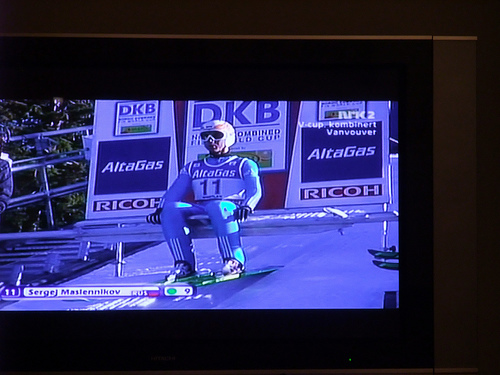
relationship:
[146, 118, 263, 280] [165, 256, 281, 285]
man on green skis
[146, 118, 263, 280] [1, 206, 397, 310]
man on ski jump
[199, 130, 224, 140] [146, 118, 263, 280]
goggles on man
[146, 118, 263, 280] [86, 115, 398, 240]
man on bench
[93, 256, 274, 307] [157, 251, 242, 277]
green skis on feet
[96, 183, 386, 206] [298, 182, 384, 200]
letters on sign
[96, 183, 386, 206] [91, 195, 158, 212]
letters on sign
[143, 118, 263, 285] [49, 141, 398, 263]
man sitting on platform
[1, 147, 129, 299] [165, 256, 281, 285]
steps besides green skis